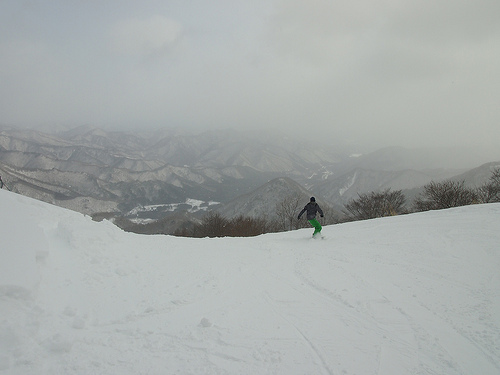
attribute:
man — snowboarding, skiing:
[294, 194, 326, 240]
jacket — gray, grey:
[297, 201, 325, 219]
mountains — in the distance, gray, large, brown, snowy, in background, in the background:
[2, 120, 499, 227]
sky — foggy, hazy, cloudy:
[2, 2, 499, 141]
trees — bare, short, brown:
[341, 187, 410, 221]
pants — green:
[308, 216, 322, 235]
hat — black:
[311, 195, 317, 202]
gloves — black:
[294, 215, 301, 220]